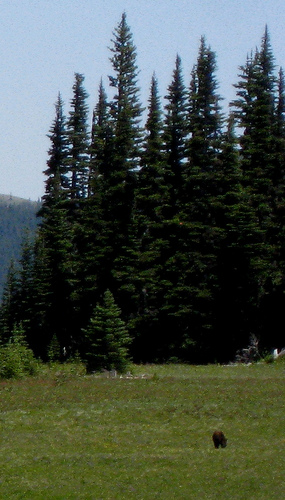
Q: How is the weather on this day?
A: It is clear.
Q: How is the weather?
A: It is clear.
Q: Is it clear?
A: Yes, it is clear.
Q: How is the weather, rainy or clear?
A: It is clear.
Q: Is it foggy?
A: No, it is clear.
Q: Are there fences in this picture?
A: No, there are no fences.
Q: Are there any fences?
A: No, there are no fences.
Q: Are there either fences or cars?
A: No, there are no fences or cars.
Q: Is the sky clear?
A: Yes, the sky is clear.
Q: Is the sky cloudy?
A: No, the sky is clear.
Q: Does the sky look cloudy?
A: No, the sky is clear.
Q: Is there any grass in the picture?
A: Yes, there is grass.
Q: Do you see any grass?
A: Yes, there is grass.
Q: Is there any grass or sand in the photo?
A: Yes, there is grass.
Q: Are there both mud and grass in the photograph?
A: No, there is grass but no mud.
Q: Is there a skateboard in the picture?
A: No, there are no skateboards.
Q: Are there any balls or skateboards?
A: No, there are no skateboards or balls.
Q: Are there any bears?
A: Yes, there is a bear.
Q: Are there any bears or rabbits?
A: Yes, there is a bear.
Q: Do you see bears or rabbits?
A: Yes, there is a bear.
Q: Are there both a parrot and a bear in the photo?
A: No, there is a bear but no parrots.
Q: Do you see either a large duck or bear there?
A: Yes, there is a large bear.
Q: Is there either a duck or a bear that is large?
A: Yes, the bear is large.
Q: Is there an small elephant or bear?
A: Yes, there is a small bear.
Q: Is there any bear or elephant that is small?
A: Yes, the bear is small.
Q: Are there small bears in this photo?
A: Yes, there is a small bear.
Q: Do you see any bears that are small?
A: Yes, there is a bear that is small.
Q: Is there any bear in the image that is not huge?
A: Yes, there is a small bear.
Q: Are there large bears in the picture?
A: Yes, there is a large bear.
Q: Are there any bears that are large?
A: Yes, there is a bear that is large.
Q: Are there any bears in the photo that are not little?
A: Yes, there is a large bear.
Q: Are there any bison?
A: No, there are no bison.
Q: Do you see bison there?
A: No, there are no bison.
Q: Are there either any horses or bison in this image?
A: No, there are no bison or horses.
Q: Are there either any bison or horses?
A: No, there are no bison or horses.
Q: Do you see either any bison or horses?
A: No, there are no bison or horses.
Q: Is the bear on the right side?
A: Yes, the bear is on the right of the image.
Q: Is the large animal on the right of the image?
A: Yes, the bear is on the right of the image.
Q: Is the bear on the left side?
A: No, the bear is on the right of the image.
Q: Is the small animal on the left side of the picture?
A: No, the bear is on the right of the image.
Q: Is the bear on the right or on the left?
A: The bear is on the right of the image.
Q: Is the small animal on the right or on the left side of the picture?
A: The bear is on the right of the image.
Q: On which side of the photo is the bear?
A: The bear is on the right of the image.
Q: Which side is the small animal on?
A: The bear is on the right of the image.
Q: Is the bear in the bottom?
A: Yes, the bear is in the bottom of the image.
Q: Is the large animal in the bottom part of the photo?
A: Yes, the bear is in the bottom of the image.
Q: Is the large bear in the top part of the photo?
A: No, the bear is in the bottom of the image.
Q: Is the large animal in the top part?
A: No, the bear is in the bottom of the image.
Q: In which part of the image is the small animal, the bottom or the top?
A: The bear is in the bottom of the image.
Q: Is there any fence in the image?
A: No, there are no fences.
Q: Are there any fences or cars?
A: No, there are no fences or cars.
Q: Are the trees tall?
A: Yes, the trees are tall.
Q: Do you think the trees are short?
A: No, the trees are tall.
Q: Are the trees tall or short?
A: The trees are tall.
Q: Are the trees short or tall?
A: The trees are tall.